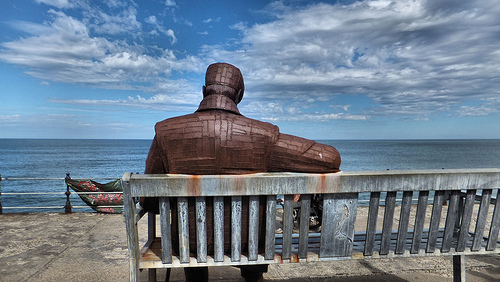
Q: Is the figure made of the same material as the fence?
A: No, the figure is made of wood and the fence is made of metal.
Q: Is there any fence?
A: Yes, there is a fence.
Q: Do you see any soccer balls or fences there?
A: Yes, there is a fence.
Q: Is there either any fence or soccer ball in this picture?
A: Yes, there is a fence.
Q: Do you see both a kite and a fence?
A: No, there is a fence but no kites.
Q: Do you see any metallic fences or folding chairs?
A: Yes, there is a metal fence.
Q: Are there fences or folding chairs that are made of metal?
A: Yes, the fence is made of metal.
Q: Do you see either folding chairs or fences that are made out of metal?
A: Yes, the fence is made of metal.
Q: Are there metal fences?
A: Yes, there is a metal fence.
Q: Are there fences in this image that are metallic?
A: Yes, there is a fence that is metallic.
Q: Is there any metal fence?
A: Yes, there is a fence that is made of metal.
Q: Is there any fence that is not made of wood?
A: Yes, there is a fence that is made of metal.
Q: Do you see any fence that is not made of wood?
A: Yes, there is a fence that is made of metal.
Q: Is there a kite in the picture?
A: No, there are no kites.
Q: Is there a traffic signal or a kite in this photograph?
A: No, there are no kites or traffic lights.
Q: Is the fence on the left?
A: Yes, the fence is on the left of the image.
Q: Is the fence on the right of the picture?
A: No, the fence is on the left of the image.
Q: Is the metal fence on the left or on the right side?
A: The fence is on the left of the image.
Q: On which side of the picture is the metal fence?
A: The fence is on the left of the image.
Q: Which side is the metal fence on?
A: The fence is on the left of the image.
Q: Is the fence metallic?
A: Yes, the fence is metallic.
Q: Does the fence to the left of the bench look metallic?
A: Yes, the fence is metallic.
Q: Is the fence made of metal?
A: Yes, the fence is made of metal.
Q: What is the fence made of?
A: The fence is made of metal.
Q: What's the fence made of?
A: The fence is made of metal.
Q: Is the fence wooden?
A: No, the fence is metallic.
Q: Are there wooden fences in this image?
A: No, there is a fence but it is metallic.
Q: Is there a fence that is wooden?
A: No, there is a fence but it is metallic.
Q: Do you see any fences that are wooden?
A: No, there is a fence but it is metallic.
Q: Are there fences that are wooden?
A: No, there is a fence but it is metallic.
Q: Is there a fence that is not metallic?
A: No, there is a fence but it is metallic.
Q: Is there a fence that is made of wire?
A: No, there is a fence but it is made of metal.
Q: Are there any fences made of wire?
A: No, there is a fence but it is made of metal.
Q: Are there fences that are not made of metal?
A: No, there is a fence but it is made of metal.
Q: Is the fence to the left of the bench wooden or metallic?
A: The fence is metallic.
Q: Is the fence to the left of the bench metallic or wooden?
A: The fence is metallic.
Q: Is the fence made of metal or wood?
A: The fence is made of metal.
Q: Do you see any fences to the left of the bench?
A: Yes, there is a fence to the left of the bench.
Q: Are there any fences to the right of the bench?
A: No, the fence is to the left of the bench.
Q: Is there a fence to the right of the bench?
A: No, the fence is to the left of the bench.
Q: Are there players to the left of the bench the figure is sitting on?
A: No, there is a fence to the left of the bench.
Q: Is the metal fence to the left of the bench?
A: Yes, the fence is to the left of the bench.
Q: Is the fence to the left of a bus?
A: No, the fence is to the left of the bench.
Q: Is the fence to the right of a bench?
A: No, the fence is to the left of a bench.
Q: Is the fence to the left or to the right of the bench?
A: The fence is to the left of the bench.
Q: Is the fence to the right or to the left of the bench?
A: The fence is to the left of the bench.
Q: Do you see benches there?
A: Yes, there is a bench.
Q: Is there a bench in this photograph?
A: Yes, there is a bench.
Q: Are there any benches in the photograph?
A: Yes, there is a bench.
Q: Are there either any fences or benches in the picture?
A: Yes, there is a bench.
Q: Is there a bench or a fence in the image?
A: Yes, there is a bench.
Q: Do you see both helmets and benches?
A: No, there is a bench but no helmets.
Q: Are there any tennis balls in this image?
A: No, there are no tennis balls.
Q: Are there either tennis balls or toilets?
A: No, there are no tennis balls or toilets.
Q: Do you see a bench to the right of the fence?
A: Yes, there is a bench to the right of the fence.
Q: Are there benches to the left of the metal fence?
A: No, the bench is to the right of the fence.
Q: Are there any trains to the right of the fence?
A: No, there is a bench to the right of the fence.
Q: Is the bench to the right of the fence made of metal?
A: Yes, the bench is to the right of the fence.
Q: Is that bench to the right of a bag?
A: No, the bench is to the right of the fence.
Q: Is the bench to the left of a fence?
A: No, the bench is to the right of a fence.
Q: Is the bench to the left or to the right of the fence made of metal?
A: The bench is to the right of the fence.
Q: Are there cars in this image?
A: No, there are no cars.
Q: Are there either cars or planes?
A: No, there are no cars or planes.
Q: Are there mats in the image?
A: No, there are no mats.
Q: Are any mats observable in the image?
A: No, there are no mats.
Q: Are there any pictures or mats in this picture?
A: No, there are no mats or pictures.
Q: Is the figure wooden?
A: Yes, the figure is wooden.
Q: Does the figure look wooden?
A: Yes, the figure is wooden.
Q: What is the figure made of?
A: The figure is made of wood.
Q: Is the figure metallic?
A: No, the figure is wooden.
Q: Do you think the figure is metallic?
A: No, the figure is wooden.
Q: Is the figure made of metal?
A: No, the figure is made of wood.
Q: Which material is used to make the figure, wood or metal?
A: The figure is made of wood.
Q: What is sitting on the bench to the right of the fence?
A: The figure is sitting on the bench.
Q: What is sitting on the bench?
A: The figure is sitting on the bench.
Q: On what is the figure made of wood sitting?
A: The figure is sitting on the bench.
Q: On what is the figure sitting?
A: The figure is sitting on the bench.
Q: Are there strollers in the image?
A: No, there are no strollers.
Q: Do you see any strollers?
A: No, there are no strollers.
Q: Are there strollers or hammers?
A: No, there are no strollers or hammers.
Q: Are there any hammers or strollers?
A: No, there are no strollers or hammers.